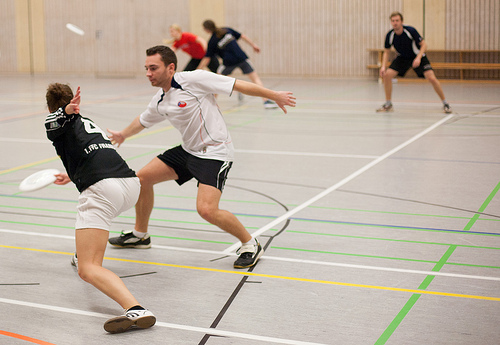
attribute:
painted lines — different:
[7, 98, 498, 343]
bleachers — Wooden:
[363, 46, 498, 86]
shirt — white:
[58, 110, 160, 207]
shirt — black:
[139, 74, 245, 160]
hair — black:
[143, 44, 178, 74]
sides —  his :
[144, 127, 233, 181]